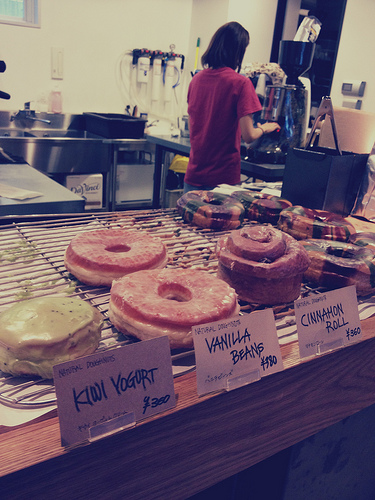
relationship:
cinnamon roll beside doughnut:
[216, 217, 309, 312] [113, 262, 270, 358]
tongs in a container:
[298, 91, 347, 156] [284, 141, 369, 235]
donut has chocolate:
[184, 189, 248, 232] [180, 192, 201, 216]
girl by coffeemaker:
[181, 12, 277, 121] [253, 24, 323, 189]